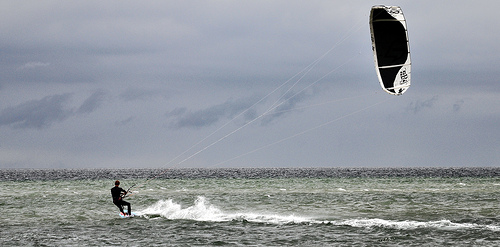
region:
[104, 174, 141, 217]
this is a man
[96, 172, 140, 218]
the man is sea surfing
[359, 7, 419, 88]
this is a kite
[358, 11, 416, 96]
the kite is black in color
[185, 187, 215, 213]
the water is splashy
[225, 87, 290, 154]
these are the ropes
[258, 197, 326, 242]
the wave is mall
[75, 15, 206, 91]
the sky is grey in color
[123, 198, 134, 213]
this is the leg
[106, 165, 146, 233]
This is a person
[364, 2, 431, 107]
This is a kite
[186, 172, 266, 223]
This is a mass of water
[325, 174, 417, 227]
This is a mass of water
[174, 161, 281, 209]
This is a mass of water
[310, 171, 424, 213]
This is a mass of water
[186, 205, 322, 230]
This is a mass of water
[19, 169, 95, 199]
This is a mass of water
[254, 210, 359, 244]
This is a mass of water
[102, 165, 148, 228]
this is a person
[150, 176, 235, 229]
this is a wave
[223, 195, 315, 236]
this is a wave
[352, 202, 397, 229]
this is a wave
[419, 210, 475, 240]
this is a wave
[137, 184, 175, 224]
this is a wave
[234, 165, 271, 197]
this is a wave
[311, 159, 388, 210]
this is a wave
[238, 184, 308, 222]
this is a wave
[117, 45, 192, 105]
sky above the man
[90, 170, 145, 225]
man in the water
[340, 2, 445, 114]
object in the air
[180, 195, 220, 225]
white water next to man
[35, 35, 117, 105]
many dark clouds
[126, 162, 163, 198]
rope held by the man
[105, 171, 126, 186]
head of the man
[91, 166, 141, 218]
man wearing a wetsuit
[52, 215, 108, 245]
waves in the water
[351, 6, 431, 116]
black and white object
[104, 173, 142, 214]
man flying a kite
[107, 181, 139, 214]
man surfing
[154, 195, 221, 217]
a small splash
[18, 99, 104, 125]
clouds in the sky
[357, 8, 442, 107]
kite is black and white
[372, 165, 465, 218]
the ocean water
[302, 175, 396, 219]
water is blue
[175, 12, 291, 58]
the sky is blue and cloudy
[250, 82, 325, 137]
white strings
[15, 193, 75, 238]
the water